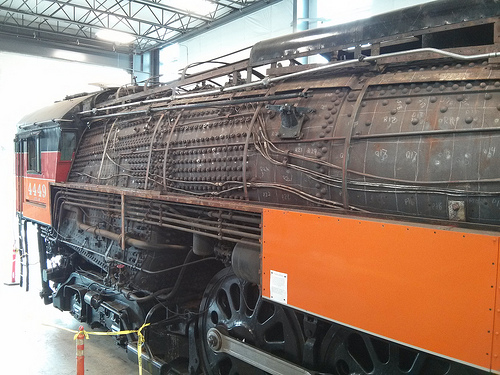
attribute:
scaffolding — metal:
[0, 3, 317, 66]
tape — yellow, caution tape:
[12, 260, 152, 375]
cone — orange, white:
[67, 323, 93, 374]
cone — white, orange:
[0, 240, 26, 286]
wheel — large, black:
[193, 266, 307, 370]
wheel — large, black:
[322, 315, 486, 375]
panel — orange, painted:
[256, 207, 499, 372]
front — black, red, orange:
[14, 82, 157, 228]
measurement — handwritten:
[365, 145, 389, 169]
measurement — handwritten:
[397, 148, 422, 168]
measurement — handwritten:
[379, 111, 402, 133]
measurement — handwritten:
[413, 93, 430, 117]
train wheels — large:
[187, 265, 321, 373]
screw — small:
[268, 271, 275, 275]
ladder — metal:
[18, 216, 28, 291]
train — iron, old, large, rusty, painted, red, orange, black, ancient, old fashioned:
[2, 0, 497, 373]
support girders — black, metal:
[1, 0, 255, 59]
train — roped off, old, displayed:
[8, 37, 495, 365]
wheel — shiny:
[196, 263, 312, 369]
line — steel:
[74, 102, 498, 212]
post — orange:
[73, 324, 88, 374]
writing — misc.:
[354, 94, 498, 204]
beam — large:
[52, 0, 182, 38]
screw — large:
[204, 333, 218, 349]